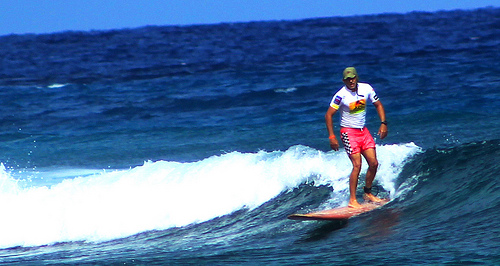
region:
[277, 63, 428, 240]
man surfing in ocean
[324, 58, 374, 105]
man wearing green cap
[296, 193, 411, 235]
red surfboard in water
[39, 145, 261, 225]
white crest of ocean wave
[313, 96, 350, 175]
man wearing orange bracelet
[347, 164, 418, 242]
surboard tethered to leg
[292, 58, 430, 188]
man in shirt and shorts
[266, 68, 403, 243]
man riding the waves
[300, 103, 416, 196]
red shorts with checks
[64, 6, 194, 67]
clear sky over ocean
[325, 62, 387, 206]
a man riding a surfboard on a sunny day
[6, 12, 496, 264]
the bright blue ocean on a sunny day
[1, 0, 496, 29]
the bright blue sky on a sunny day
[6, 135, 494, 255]
the wave the man is riding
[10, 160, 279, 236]
the foamy part of the wave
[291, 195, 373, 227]
the red surfboard the man is riding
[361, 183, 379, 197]
the cord attached to the man's ankle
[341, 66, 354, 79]
the hat on the man's head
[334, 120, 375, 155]
the pink shorts the man is wearing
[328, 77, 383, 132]
the white shirt the man has on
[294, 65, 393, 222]
Man on surfboard in the ocean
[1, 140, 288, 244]
Wave breaking in the ocean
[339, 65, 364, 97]
Man wearing a green hat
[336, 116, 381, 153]
Man wearing red shorts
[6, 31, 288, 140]
Dark blue ocean water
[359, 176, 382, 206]
Ankle strap connected to the surfboard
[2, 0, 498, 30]
Light blue sky at the horizon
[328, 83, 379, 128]
Man wearing a white t-shirt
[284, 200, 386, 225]
Red surfboard sticking out of the water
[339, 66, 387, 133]
Man wearing a black watch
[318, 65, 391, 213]
a man standing on a surfboard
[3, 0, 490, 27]
the bright blue sky above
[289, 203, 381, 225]
the red surfboard in the water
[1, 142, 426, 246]
the foamy part of the wave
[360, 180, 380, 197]
the cord on the man's ankle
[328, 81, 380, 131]
the white shirt the man is wearing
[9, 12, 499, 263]
the bright blue ocean with waves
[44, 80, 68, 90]
a white spot in the water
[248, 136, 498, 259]
the rest of the wave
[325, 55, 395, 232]
The man is standing on the surfboard.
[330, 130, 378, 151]
the man is wearing red trunks.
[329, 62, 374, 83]
The man is wearing a cap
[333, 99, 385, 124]
The shirt is very colorful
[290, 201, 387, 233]
The surfboard is in the water.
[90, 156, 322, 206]
The waves are white.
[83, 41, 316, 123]
The wate is a dark blue.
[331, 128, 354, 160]
The shorts are black and white on the side.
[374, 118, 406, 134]
The man is wearing a watch.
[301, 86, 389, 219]
The man is riding the wave.